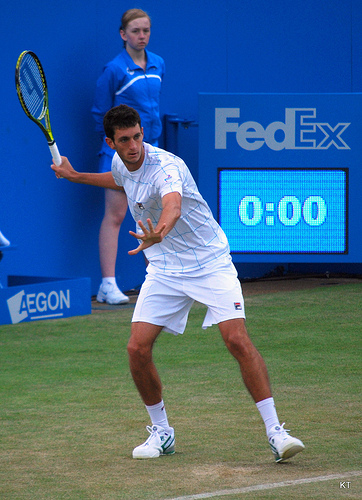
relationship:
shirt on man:
[113, 161, 222, 260] [87, 110, 252, 312]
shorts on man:
[131, 254, 246, 336] [71, 36, 300, 460]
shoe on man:
[132, 423, 175, 458] [50, 103, 306, 464]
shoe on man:
[267, 420, 304, 461] [50, 103, 306, 464]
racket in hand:
[14, 49, 65, 159] [50, 155, 70, 181]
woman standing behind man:
[92, 9, 165, 305] [50, 103, 306, 464]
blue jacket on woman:
[90, 48, 165, 158] [90, 4, 193, 312]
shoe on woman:
[88, 274, 133, 311] [97, 18, 193, 162]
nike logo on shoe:
[101, 286, 108, 296] [94, 278, 130, 304]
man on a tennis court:
[50, 103, 306, 464] [2, 5, 351, 488]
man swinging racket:
[50, 103, 306, 464] [14, 46, 63, 172]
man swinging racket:
[105, 0, 190, 124] [10, 44, 68, 176]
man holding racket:
[50, 103, 306, 464] [10, 44, 68, 176]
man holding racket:
[50, 103, 306, 464] [14, 46, 63, 172]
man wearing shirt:
[50, 103, 306, 464] [110, 139, 231, 273]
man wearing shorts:
[50, 103, 306, 464] [131, 254, 246, 336]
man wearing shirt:
[50, 103, 306, 464] [96, 146, 226, 273]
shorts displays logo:
[133, 257, 245, 330] [234, 299, 244, 313]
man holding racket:
[50, 103, 306, 464] [11, 47, 61, 165]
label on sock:
[161, 406, 165, 410] [255, 397, 280, 436]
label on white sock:
[161, 406, 165, 410] [142, 401, 170, 425]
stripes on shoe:
[154, 434, 178, 455] [132, 425, 175, 459]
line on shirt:
[169, 449, 361, 498] [99, 152, 247, 274]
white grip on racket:
[48, 140, 62, 165] [16, 50, 64, 165]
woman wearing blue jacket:
[97, 14, 182, 218] [101, 51, 160, 141]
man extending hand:
[50, 103, 306, 464] [127, 215, 178, 256]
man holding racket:
[50, 103, 306, 464] [4, 41, 71, 168]